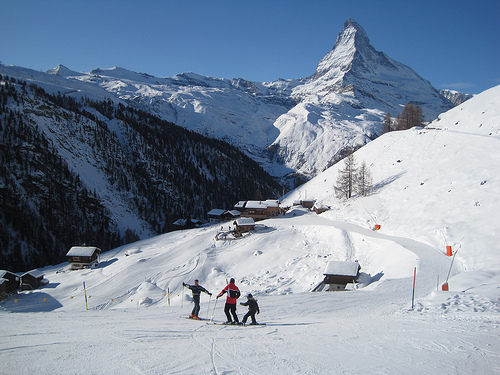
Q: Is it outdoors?
A: Yes, it is outdoors.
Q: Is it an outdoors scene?
A: Yes, it is outdoors.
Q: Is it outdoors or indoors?
A: It is outdoors.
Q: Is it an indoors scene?
A: No, it is outdoors.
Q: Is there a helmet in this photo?
A: No, there are no helmets.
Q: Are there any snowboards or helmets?
A: No, there are no helmets or snowboards.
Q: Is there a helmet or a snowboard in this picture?
A: No, there are no helmets or snowboards.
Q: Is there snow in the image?
A: Yes, there is snow.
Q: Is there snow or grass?
A: Yes, there is snow.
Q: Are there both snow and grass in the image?
A: No, there is snow but no grass.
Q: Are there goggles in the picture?
A: No, there are no goggles.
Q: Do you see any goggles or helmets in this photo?
A: No, there are no goggles or helmets.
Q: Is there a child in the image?
A: Yes, there is a child.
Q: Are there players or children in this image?
A: Yes, there is a child.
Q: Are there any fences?
A: No, there are no fences.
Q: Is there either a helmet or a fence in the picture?
A: No, there are no fences or helmets.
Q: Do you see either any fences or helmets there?
A: No, there are no fences or helmets.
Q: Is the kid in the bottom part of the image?
A: Yes, the kid is in the bottom of the image.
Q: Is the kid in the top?
A: No, the kid is in the bottom of the image.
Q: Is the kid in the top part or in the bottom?
A: The kid is in the bottom of the image.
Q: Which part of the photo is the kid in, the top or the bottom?
A: The kid is in the bottom of the image.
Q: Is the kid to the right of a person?
A: Yes, the kid is to the right of a person.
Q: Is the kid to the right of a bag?
A: No, the kid is to the right of a person.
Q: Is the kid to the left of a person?
A: No, the kid is to the right of a person.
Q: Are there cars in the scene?
A: No, there are no cars.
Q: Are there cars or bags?
A: No, there are no cars or bags.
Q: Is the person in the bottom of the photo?
A: Yes, the person is in the bottom of the image.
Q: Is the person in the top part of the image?
A: No, the person is in the bottom of the image.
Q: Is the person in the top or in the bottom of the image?
A: The person is in the bottom of the image.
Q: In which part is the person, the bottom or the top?
A: The person is in the bottom of the image.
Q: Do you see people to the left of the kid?
A: Yes, there is a person to the left of the kid.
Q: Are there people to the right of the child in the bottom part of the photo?
A: No, the person is to the left of the kid.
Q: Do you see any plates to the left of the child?
A: No, there is a person to the left of the child.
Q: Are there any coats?
A: Yes, there is a coat.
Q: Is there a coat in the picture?
A: Yes, there is a coat.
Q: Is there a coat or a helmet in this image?
A: Yes, there is a coat.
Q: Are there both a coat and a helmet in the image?
A: No, there is a coat but no helmets.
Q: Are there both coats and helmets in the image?
A: No, there is a coat but no helmets.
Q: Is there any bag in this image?
A: No, there are no bags.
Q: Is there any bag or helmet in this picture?
A: No, there are no bags or helmets.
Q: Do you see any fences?
A: No, there are no fences.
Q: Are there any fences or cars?
A: No, there are no fences or cars.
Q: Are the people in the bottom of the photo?
A: Yes, the people are in the bottom of the image.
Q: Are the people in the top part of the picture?
A: No, the people are in the bottom of the image.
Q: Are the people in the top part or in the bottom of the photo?
A: The people are in the bottom of the image.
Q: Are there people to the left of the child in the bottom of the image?
A: Yes, there are people to the left of the child.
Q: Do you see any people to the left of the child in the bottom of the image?
A: Yes, there are people to the left of the child.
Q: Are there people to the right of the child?
A: No, the people are to the left of the child.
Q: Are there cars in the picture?
A: No, there are no cars.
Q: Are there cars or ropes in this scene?
A: No, there are no cars or ropes.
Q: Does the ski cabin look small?
A: Yes, the cabin is small.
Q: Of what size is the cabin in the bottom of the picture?
A: The cabin is small.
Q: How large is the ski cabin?
A: The cabin is small.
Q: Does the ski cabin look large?
A: No, the cabin is small.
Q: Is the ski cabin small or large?
A: The cabin is small.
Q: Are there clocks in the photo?
A: No, there are no clocks.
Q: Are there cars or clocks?
A: No, there are no clocks or cars.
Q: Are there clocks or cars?
A: No, there are no clocks or cars.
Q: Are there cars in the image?
A: No, there are no cars.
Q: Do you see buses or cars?
A: No, there are no cars or buses.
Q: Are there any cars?
A: No, there are no cars.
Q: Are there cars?
A: No, there are no cars.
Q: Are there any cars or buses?
A: No, there are no cars or buses.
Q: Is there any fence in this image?
A: No, there are no fences.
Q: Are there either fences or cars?
A: No, there are no fences or cars.